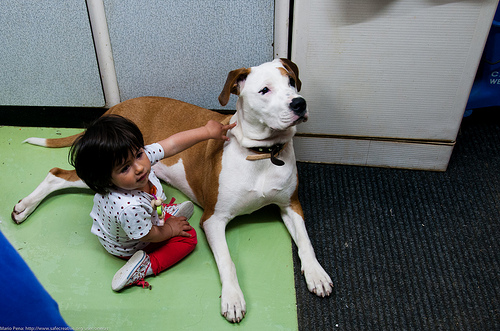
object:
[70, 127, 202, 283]
child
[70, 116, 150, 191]
head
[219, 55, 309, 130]
head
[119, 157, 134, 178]
eye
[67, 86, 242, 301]
face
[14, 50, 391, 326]
dog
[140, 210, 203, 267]
pants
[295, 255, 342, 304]
paw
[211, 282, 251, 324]
paw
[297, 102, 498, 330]
floor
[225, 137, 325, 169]
collar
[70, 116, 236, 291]
girl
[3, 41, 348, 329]
pitt bull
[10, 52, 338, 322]
large dog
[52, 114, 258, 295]
person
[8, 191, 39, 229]
paw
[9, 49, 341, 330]
animal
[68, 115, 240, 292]
little girl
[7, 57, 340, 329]
big dog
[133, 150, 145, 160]
eye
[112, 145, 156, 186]
face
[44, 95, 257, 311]
toddler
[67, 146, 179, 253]
shirt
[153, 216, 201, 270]
pants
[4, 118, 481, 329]
floor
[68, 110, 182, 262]
body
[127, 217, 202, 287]
girl's leg